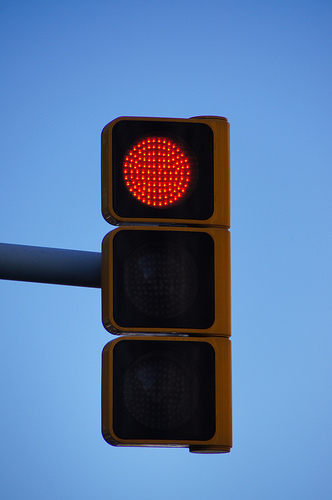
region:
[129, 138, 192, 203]
the red traffic light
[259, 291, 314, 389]
the blue skies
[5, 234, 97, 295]
the metal bar of a traffic light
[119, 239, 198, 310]
an off traffic light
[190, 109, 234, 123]
the top of a traffic light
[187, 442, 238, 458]
the bottom of a traffic light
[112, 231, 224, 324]
the yellow part of the traffic light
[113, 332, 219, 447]
the green light of a traffic light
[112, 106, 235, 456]
3 light signal stack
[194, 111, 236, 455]
the body of a traffic light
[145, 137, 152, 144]
small red colored light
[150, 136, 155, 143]
small red colored light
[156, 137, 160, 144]
small red colored light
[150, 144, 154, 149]
small red colored light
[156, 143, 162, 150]
small red colored light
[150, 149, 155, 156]
small red colored light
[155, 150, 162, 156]
small red colored light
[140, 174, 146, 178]
small red colored light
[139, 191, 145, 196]
small red colored light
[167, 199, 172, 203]
small red colored light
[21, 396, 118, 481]
A blue sky background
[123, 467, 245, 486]
A blue sky background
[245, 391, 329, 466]
A blue sky background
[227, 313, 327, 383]
A blue sky background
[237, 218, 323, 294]
A blue sky background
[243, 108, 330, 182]
A blue sky background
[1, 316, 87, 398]
A blue sky background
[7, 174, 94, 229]
A blue sky background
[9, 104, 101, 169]
A blue sky background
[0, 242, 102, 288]
the pole holding up the traffic light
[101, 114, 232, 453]
the yellow casing for the traffic light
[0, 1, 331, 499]
the clear blue sky behind the traffic light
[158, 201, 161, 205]
the red pixel on the traffic light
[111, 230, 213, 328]
the black area in the traffic light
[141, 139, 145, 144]
the red pixel on the traffic light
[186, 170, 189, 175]
the red pixel on the traffic light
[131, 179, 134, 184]
the red pixel on the traffic light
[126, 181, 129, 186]
the red pixel on the traffic light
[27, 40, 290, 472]
traffic light attached to a pole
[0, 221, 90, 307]
metal pole perpendicular to the lights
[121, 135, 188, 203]
circular red light composed of many small lights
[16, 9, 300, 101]
background of a blue sky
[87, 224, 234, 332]
middle light turned off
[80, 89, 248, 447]
traffic control signal with red light on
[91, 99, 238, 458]
traffic lamp with three aspects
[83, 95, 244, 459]
red light facing a driver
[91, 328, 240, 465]
bottom green light, currently off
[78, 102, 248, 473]
traffic semaphore, attached to a pole